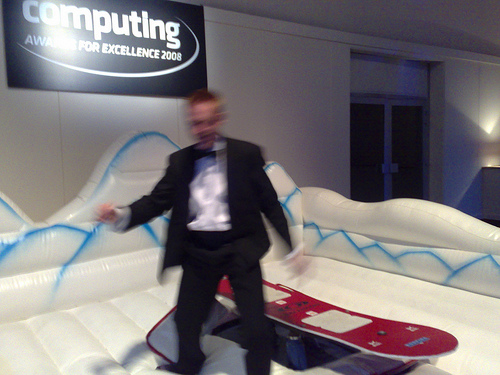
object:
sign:
[0, 0, 209, 101]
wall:
[0, 0, 500, 223]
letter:
[91, 9, 112, 42]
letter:
[163, 21, 182, 50]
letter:
[128, 10, 143, 40]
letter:
[60, 4, 92, 33]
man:
[92, 89, 306, 375]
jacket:
[110, 134, 299, 285]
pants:
[171, 229, 273, 375]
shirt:
[185, 135, 232, 233]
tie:
[192, 146, 217, 161]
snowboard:
[214, 271, 459, 372]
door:
[347, 90, 432, 204]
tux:
[120, 137, 296, 375]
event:
[0, 0, 499, 375]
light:
[483, 163, 499, 169]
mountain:
[0, 129, 301, 277]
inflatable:
[0, 129, 500, 373]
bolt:
[377, 329, 386, 336]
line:
[488, 255, 500, 268]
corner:
[483, 54, 500, 165]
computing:
[21, 0, 184, 50]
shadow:
[442, 103, 499, 221]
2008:
[160, 50, 183, 62]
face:
[182, 98, 219, 146]